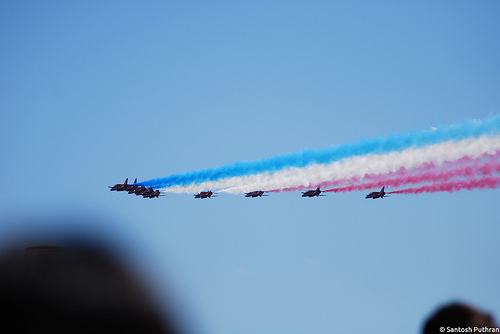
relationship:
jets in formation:
[193, 189, 215, 200] [99, 169, 389, 207]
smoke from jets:
[161, 105, 499, 199] [193, 189, 215, 200]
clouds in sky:
[168, 113, 482, 213] [7, 7, 489, 331]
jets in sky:
[111, 172, 392, 205] [7, 7, 489, 331]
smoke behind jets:
[161, 105, 499, 199] [111, 172, 392, 205]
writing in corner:
[437, 313, 498, 334] [426, 302, 485, 332]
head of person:
[13, 227, 165, 333] [5, 243, 128, 333]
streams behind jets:
[176, 100, 498, 190] [193, 189, 215, 200]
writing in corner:
[437, 324, 499, 334] [426, 302, 485, 332]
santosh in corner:
[446, 325, 468, 334] [426, 302, 485, 332]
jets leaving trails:
[111, 172, 392, 205] [168, 111, 494, 204]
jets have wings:
[111, 172, 392, 205] [156, 194, 171, 201]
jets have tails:
[111, 172, 392, 205] [381, 183, 388, 194]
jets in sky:
[193, 189, 215, 200] [7, 7, 489, 331]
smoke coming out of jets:
[161, 105, 499, 199] [193, 189, 215, 200]